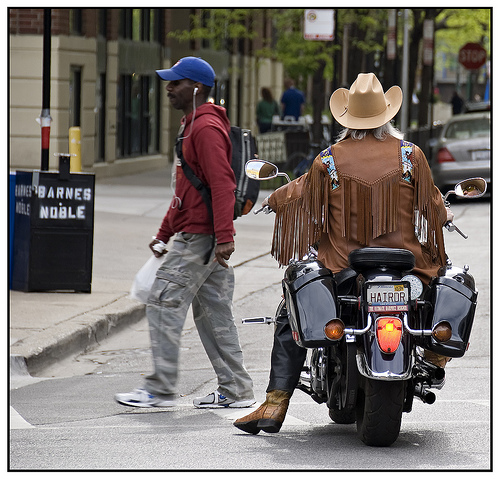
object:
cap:
[154, 53, 218, 89]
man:
[112, 53, 257, 411]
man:
[232, 70, 454, 436]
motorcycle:
[240, 158, 482, 447]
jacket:
[269, 136, 449, 275]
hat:
[328, 69, 405, 130]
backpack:
[224, 124, 261, 215]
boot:
[230, 387, 300, 438]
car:
[435, 111, 490, 200]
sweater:
[152, 101, 241, 249]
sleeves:
[193, 123, 239, 238]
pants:
[146, 227, 255, 406]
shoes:
[191, 385, 258, 409]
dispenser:
[10, 168, 95, 292]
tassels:
[267, 204, 331, 266]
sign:
[436, 41, 487, 82]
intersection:
[306, 21, 495, 177]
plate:
[360, 279, 411, 313]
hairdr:
[366, 282, 412, 306]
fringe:
[270, 169, 331, 265]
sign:
[36, 183, 93, 220]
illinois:
[368, 304, 410, 311]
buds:
[187, 87, 199, 138]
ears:
[191, 81, 203, 95]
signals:
[322, 312, 375, 343]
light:
[373, 313, 406, 354]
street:
[10, 206, 491, 384]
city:
[10, 9, 489, 469]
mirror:
[452, 173, 488, 199]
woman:
[231, 69, 490, 450]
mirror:
[242, 158, 280, 180]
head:
[164, 60, 215, 110]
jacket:
[155, 101, 236, 247]